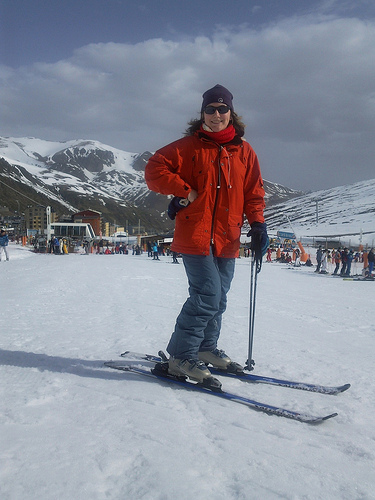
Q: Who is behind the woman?
A: A crowd.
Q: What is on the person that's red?
A: Coat.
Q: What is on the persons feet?
A: Skis.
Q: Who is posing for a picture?
A: The woman in front.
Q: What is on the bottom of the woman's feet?
A: Blue skis.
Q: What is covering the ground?
A: Snow.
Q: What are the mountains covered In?
A: Snow.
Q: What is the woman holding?
A: Ski poles.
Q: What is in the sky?
A: Clouds.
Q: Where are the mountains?
A: Behind the ski lodge.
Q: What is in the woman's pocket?
A: Her hand.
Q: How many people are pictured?
A: One.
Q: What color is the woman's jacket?
A: Red.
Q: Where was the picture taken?
A: Ski resort.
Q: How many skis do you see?
A: Two.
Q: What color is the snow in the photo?
A: White.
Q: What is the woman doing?
A: Standing.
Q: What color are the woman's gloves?
A: Black.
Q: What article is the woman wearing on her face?
A: Sunglasses.